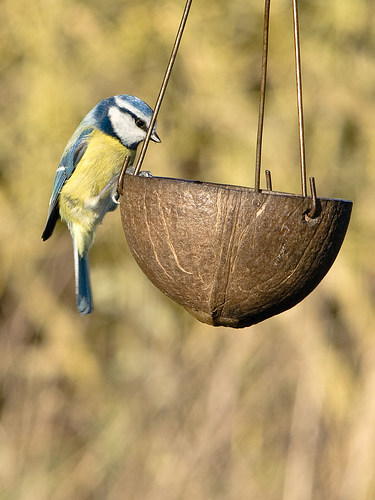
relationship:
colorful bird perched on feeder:
[43, 87, 157, 266] [115, 203, 245, 293]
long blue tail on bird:
[62, 216, 102, 318] [41, 97, 156, 331]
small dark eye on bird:
[129, 116, 150, 129] [41, 92, 169, 266]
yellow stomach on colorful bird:
[66, 135, 128, 220] [44, 89, 144, 319]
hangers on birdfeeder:
[159, 101, 305, 122] [138, 192, 332, 241]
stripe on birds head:
[117, 108, 154, 135] [93, 96, 177, 147]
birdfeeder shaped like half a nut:
[146, 234, 297, 298] [177, 264, 244, 307]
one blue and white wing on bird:
[52, 138, 70, 212] [34, 95, 163, 397]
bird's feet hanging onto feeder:
[87, 160, 140, 235] [93, 204, 328, 330]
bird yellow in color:
[39, 88, 156, 282] [77, 137, 119, 238]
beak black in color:
[146, 122, 167, 150] [81, 102, 164, 197]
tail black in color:
[70, 249, 91, 328] [38, 255, 95, 344]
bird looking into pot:
[39, 88, 161, 313] [106, 183, 353, 373]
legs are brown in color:
[101, 166, 149, 220] [103, 156, 146, 245]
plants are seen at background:
[35, 326, 161, 469] [10, 309, 363, 500]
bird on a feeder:
[39, 88, 161, 313] [108, 183, 341, 310]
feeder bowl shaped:
[131, 187, 331, 337] [120, 183, 350, 329]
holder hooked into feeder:
[299, 184, 318, 224] [122, 177, 340, 332]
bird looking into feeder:
[39, 88, 161, 313] [118, 230, 332, 347]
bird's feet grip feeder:
[111, 165, 153, 206] [115, 231, 306, 361]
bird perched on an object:
[39, 88, 161, 313] [132, 230, 291, 361]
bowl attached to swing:
[120, 160, 354, 332] [141, 74, 338, 211]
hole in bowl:
[292, 176, 317, 238] [101, 156, 340, 341]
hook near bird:
[115, 174, 129, 230] [42, 89, 152, 339]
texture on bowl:
[170, 244, 251, 293] [118, 162, 342, 301]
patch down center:
[197, 185, 255, 319] [163, 166, 291, 340]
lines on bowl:
[168, 205, 310, 271] [129, 160, 344, 323]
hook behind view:
[264, 171, 277, 184] [221, 159, 324, 264]